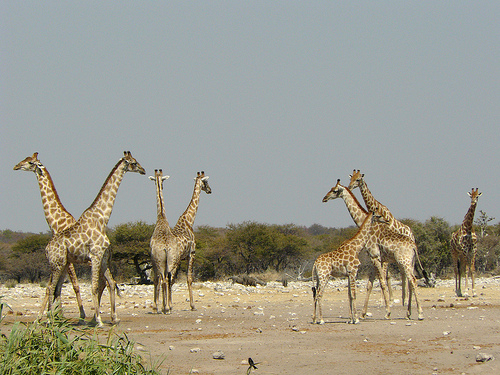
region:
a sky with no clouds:
[1, 0, 496, 230]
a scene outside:
[7, 6, 474, 373]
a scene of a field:
[5, 8, 495, 353]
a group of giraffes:
[2, 130, 497, 338]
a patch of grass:
[0, 288, 172, 373]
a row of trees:
[2, 193, 497, 296]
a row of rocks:
[6, 264, 498, 348]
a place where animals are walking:
[3, 4, 493, 368]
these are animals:
[9, 112, 497, 358]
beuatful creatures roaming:
[12, 126, 497, 328]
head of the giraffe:
[114, 139, 151, 186]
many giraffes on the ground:
[23, 129, 482, 311]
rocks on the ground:
[237, 291, 291, 339]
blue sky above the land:
[200, 96, 315, 188]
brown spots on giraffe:
[311, 246, 357, 293]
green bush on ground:
[11, 317, 93, 374]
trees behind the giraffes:
[215, 214, 295, 284]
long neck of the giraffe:
[88, 148, 145, 222]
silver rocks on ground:
[212, 276, 247, 308]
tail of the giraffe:
[296, 265, 324, 301]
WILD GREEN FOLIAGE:
[4, 345, 138, 374]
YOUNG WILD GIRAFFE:
[296, 202, 373, 327]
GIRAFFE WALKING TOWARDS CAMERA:
[443, 185, 488, 302]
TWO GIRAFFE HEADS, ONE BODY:
[12, 147, 142, 337]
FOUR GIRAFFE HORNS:
[152, 167, 212, 179]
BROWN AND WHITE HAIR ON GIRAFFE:
[76, 222, 106, 249]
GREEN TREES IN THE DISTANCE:
[221, 221, 298, 282]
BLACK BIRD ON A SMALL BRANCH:
[241, 356, 264, 371]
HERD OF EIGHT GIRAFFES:
[6, 135, 486, 337]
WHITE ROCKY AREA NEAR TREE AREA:
[207, 280, 302, 305]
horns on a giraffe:
[121, 148, 131, 155]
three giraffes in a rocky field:
[311, 165, 434, 327]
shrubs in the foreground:
[1, 315, 145, 373]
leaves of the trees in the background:
[222, 222, 305, 262]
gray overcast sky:
[0, 2, 491, 145]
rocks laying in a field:
[208, 277, 294, 294]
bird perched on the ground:
[240, 355, 267, 372]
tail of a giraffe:
[410, 238, 432, 286]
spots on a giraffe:
[331, 246, 351, 272]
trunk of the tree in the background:
[130, 254, 152, 285]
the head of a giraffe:
[113, 145, 150, 178]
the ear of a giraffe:
[159, 171, 172, 183]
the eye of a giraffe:
[25, 157, 35, 166]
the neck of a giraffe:
[76, 162, 131, 225]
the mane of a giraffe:
[82, 155, 122, 211]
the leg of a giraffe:
[179, 251, 205, 307]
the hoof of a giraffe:
[91, 317, 110, 330]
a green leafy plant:
[1, 282, 172, 373]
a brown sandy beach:
[3, 277, 498, 372]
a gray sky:
[1, 0, 498, 238]